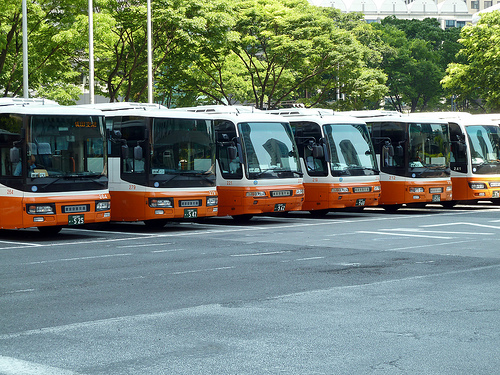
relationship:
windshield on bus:
[151, 120, 215, 184] [77, 103, 219, 231]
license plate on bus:
[184, 211, 198, 219] [77, 103, 219, 231]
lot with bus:
[4, 200, 498, 373] [77, 103, 219, 231]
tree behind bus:
[91, 2, 199, 102] [77, 103, 219, 231]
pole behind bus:
[146, 2, 153, 105] [77, 103, 219, 231]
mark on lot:
[233, 250, 293, 257] [4, 200, 498, 373]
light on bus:
[151, 198, 172, 207] [77, 103, 219, 231]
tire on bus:
[145, 219, 169, 227] [77, 103, 219, 231]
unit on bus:
[89, 99, 168, 110] [77, 103, 219, 231]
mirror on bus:
[132, 140, 146, 160] [77, 103, 219, 231]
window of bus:
[110, 117, 145, 176] [77, 103, 219, 231]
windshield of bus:
[239, 121, 302, 178] [179, 104, 303, 221]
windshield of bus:
[325, 122, 378, 177] [261, 108, 382, 217]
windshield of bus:
[151, 120, 215, 184] [77, 103, 219, 231]